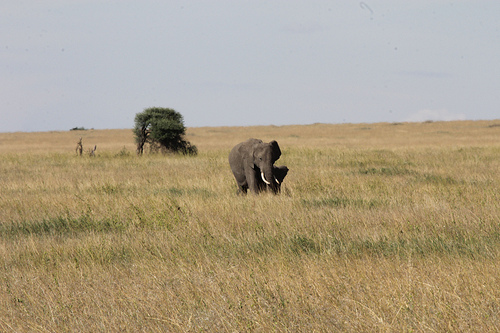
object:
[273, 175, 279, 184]
tusk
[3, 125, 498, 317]
area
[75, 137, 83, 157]
trunk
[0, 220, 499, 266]
strip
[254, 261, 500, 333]
grass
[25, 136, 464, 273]
plains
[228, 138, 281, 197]
elephant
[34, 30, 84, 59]
clouds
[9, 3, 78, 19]
sky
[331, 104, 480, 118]
sky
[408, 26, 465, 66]
clouds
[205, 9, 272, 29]
clouds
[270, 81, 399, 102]
sky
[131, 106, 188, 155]
tree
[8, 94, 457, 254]
scene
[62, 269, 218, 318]
grass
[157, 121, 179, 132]
leaves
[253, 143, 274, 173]
head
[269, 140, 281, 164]
ear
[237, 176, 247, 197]
leg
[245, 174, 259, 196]
leg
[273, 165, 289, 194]
shadow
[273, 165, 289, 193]
elephant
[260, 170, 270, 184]
tusk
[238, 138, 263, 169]
ear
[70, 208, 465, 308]
field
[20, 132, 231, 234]
field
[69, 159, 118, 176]
grass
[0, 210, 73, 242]
grass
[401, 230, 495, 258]
grass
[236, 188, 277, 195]
elephant feet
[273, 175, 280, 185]
elephant tusks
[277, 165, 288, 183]
elephant ear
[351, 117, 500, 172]
grass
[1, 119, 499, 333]
land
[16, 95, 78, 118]
sky